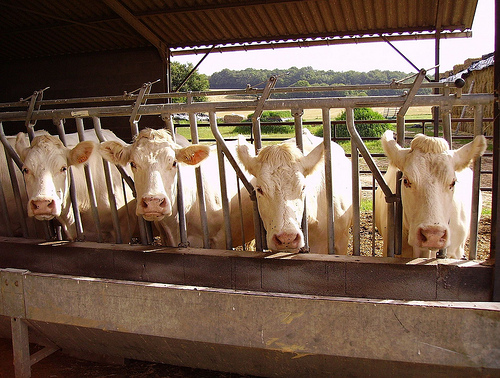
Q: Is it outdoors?
A: Yes, it is outdoors.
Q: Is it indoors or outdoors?
A: It is outdoors.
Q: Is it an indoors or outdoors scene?
A: It is outdoors.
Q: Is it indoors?
A: No, it is outdoors.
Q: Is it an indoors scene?
A: No, it is outdoors.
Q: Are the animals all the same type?
A: Yes, all the animals are cows.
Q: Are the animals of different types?
A: No, all the animals are cows.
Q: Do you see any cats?
A: No, there are no cats.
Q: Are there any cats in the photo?
A: No, there are no cats.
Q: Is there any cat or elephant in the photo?
A: No, there are no cats or elephants.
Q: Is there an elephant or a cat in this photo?
A: No, there are no cats or elephants.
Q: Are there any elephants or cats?
A: No, there are no cats or elephants.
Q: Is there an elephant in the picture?
A: No, there are no elephants.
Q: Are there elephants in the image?
A: No, there are no elephants.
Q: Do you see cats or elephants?
A: No, there are no elephants or cats.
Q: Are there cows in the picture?
A: Yes, there is a cow.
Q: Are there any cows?
A: Yes, there is a cow.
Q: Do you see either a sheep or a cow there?
A: Yes, there is a cow.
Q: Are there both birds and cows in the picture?
A: No, there is a cow but no birds.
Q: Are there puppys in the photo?
A: No, there are no puppys.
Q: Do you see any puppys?
A: No, there are no puppys.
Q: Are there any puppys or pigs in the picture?
A: No, there are no puppys or pigs.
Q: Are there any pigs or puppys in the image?
A: No, there are no puppys or pigs.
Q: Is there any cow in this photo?
A: Yes, there is a cow.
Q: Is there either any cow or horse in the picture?
A: Yes, there is a cow.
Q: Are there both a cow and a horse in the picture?
A: No, there is a cow but no horses.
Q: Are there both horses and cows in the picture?
A: No, there is a cow but no horses.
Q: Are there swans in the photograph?
A: No, there are no swans.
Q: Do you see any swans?
A: No, there are no swans.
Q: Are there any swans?
A: No, there are no swans.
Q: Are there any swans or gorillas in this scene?
A: No, there are no swans or gorillas.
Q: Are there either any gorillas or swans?
A: No, there are no swans or gorillas.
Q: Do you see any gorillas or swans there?
A: No, there are no swans or gorillas.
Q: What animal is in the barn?
A: The cow is in the barn.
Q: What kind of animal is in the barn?
A: The animal is a cow.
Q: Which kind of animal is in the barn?
A: The animal is a cow.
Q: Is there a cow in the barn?
A: Yes, there is a cow in the barn.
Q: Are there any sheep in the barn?
A: No, there is a cow in the barn.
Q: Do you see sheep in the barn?
A: No, there is a cow in the barn.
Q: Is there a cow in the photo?
A: Yes, there is a cow.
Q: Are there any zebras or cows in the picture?
A: Yes, there is a cow.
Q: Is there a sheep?
A: No, there is no sheep.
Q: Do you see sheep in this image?
A: No, there are no sheep.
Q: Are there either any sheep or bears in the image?
A: No, there are no sheep or bears.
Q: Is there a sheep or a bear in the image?
A: No, there are no sheep or bears.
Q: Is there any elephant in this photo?
A: No, there are no elephants.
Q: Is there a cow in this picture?
A: Yes, there is a cow.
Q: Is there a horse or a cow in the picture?
A: Yes, there is a cow.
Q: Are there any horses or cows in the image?
A: Yes, there is a cow.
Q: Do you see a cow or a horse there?
A: Yes, there is a cow.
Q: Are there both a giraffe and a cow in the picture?
A: No, there is a cow but no giraffes.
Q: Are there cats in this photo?
A: No, there are no cats.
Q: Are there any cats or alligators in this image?
A: No, there are no cats or alligators.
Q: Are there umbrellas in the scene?
A: No, there are no umbrellas.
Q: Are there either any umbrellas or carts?
A: No, there are no umbrellas or carts.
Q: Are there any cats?
A: No, there are no cats.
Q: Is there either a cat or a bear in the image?
A: No, there are no cats or bears.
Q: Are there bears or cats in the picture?
A: No, there are no cats or bears.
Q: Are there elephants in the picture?
A: No, there are no elephants.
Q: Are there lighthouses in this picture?
A: No, there are no lighthouses.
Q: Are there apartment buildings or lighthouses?
A: No, there are no lighthouses or apartment buildings.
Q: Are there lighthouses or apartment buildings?
A: No, there are no lighthouses or apartment buildings.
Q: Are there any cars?
A: No, there are no cars.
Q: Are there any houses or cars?
A: No, there are no cars or houses.